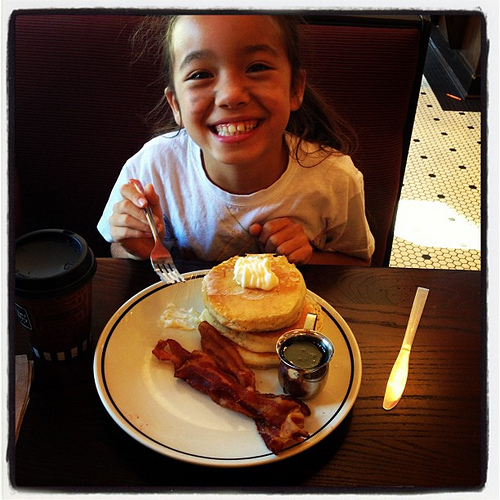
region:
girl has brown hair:
[97, 6, 349, 55]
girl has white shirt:
[113, 103, 315, 250]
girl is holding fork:
[122, 153, 181, 294]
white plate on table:
[182, 290, 344, 485]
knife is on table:
[347, 282, 454, 452]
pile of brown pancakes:
[224, 247, 331, 389]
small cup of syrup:
[254, 308, 327, 400]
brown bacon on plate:
[155, 323, 296, 454]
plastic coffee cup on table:
[0, 204, 98, 380]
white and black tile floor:
[401, 124, 498, 271]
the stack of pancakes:
[201, 258, 328, 372]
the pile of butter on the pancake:
[231, 251, 280, 294]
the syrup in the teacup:
[275, 327, 337, 400]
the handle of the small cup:
[303, 309, 320, 335]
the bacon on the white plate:
[145, 322, 280, 451]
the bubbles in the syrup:
[291, 346, 323, 364]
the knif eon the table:
[379, 283, 431, 416]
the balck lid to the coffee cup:
[10, 227, 100, 287]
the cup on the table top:
[16, 277, 94, 368]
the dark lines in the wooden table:
[411, 316, 464, 469]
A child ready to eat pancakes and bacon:
[83, 24, 372, 474]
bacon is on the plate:
[163, 336, 301, 430]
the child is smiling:
[101, 40, 375, 268]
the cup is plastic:
[6, 227, 103, 369]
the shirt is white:
[108, 148, 370, 269]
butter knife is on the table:
[390, 286, 427, 426]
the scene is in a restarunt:
[18, 27, 475, 473]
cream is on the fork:
[154, 267, 186, 288]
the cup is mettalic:
[278, 315, 343, 402]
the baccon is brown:
[163, 336, 305, 448]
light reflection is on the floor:
[396, 194, 476, 264]